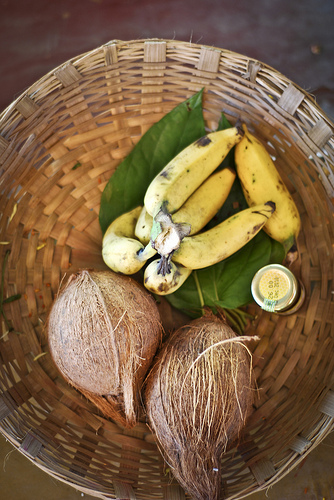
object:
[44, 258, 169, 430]
hairy coconuts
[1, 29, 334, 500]
basket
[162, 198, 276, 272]
bananas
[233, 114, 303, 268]
banana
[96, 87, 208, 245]
green leaf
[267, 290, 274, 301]
26 of dec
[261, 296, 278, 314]
sticker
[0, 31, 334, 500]
table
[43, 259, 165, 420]
coconut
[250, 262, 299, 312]
cap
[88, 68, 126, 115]
side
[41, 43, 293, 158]
wicker basket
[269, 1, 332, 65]
orange flecks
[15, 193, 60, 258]
yellow flecks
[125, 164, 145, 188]
leaf stem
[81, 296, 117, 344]
brown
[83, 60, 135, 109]
woven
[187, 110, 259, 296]
leaves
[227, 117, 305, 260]
fruit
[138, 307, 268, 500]
hairy coconut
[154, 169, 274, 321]
green leaves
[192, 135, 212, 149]
brown spot